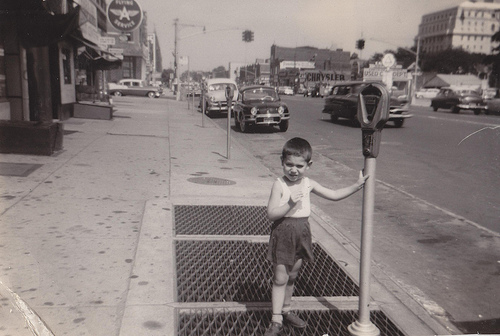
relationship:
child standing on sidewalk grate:
[265, 136, 372, 335] [173, 201, 407, 334]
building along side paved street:
[411, 2, 498, 80] [183, 83, 500, 335]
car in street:
[228, 79, 293, 141] [192, 80, 492, 320]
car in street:
[194, 72, 240, 117] [192, 80, 492, 320]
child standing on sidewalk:
[265, 136, 372, 335] [109, 96, 187, 334]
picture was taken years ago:
[104, 26, 394, 258] [104, 50, 386, 336]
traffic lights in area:
[167, 8, 420, 63] [54, 108, 306, 184]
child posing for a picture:
[256, 129, 353, 314] [0, 0, 500, 334]